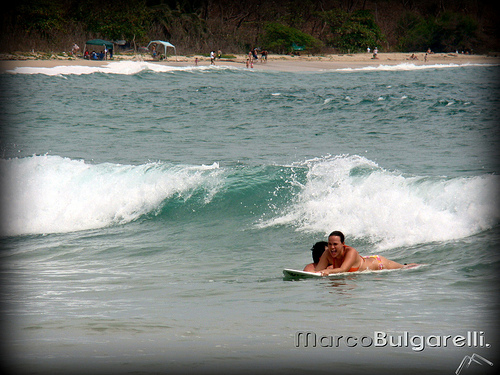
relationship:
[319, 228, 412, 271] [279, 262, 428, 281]
girl on surfboard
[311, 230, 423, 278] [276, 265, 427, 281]
girl on surfboard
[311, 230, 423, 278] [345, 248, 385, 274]
girl wearing bikini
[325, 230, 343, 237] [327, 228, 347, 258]
hair on head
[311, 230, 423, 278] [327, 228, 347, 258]
girl has head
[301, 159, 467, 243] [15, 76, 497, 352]
wave in water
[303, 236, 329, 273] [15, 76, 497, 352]
man swimming in water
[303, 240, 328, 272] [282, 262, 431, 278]
man holding onto surfboard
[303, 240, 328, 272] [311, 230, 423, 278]
man next to girl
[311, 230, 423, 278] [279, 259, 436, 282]
girl on surfboard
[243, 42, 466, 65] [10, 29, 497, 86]
people are on beach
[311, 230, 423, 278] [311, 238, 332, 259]
girl has head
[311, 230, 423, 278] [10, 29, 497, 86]
girl on beach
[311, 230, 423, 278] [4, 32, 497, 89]
girl on beach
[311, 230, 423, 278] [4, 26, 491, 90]
girl on beach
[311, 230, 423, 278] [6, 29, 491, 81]
girl on beach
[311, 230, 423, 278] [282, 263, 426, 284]
girl on surfboard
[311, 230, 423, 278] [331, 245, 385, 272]
girl wearing bikini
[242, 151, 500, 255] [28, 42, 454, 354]
wave in water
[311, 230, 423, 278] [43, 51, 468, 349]
girl in water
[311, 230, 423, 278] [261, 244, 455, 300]
girl on surfboard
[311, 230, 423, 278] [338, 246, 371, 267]
girl with bikini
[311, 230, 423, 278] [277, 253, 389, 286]
girl on surfboard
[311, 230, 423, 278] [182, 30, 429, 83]
girl at shore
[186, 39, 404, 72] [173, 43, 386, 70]
people at shore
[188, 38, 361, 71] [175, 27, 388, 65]
people at shore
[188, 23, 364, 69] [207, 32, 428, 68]
people at shore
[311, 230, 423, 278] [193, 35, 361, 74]
girl at shore